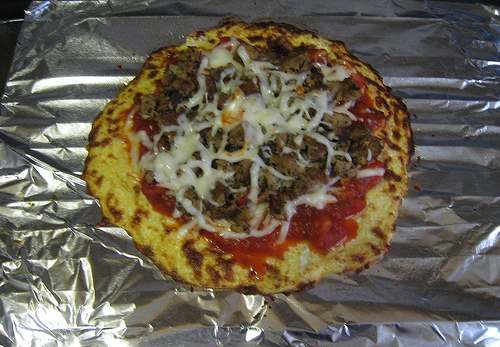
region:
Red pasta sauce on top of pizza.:
[277, 242, 328, 243]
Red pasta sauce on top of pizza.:
[234, 261, 285, 286]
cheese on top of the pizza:
[140, 44, 335, 250]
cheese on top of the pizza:
[135, 46, 319, 226]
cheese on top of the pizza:
[160, 59, 333, 244]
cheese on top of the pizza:
[166, 83, 324, 213]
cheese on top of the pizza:
[152, 61, 319, 237]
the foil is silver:
[14, 31, 114, 336]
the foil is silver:
[358, 139, 444, 341]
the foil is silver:
[375, 185, 460, 340]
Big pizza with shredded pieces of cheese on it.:
[275, 134, 320, 181]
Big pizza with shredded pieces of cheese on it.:
[52, 133, 100, 199]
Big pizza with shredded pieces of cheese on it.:
[303, 97, 325, 141]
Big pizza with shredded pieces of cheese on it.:
[290, 190, 307, 325]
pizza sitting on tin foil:
[6, 5, 499, 344]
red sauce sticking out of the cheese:
[216, 232, 282, 272]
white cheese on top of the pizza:
[135, 45, 385, 240]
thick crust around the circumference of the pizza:
[75, 15, 424, 290]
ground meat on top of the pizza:
[120, 38, 390, 236]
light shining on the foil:
[16, 270, 127, 342]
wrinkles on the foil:
[0, 0, 499, 344]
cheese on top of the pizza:
[138, 32, 385, 254]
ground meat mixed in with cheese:
[104, 28, 401, 248]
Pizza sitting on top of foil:
[85, 18, 416, 295]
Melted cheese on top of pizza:
[128, 40, 385, 242]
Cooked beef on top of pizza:
[143, 52, 204, 117]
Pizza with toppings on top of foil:
[85, 22, 417, 297]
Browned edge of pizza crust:
[365, 70, 410, 190]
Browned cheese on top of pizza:
[215, 85, 245, 126]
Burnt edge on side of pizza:
[225, 20, 315, 40]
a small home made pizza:
[84, 19, 416, 298]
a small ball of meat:
[136, 91, 156, 115]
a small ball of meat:
[329, 113, 351, 130]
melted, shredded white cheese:
[142, 39, 364, 234]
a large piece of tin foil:
[12, 3, 496, 343]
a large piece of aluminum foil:
[7, 2, 499, 344]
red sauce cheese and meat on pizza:
[90, 85, 150, 127]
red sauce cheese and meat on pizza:
[106, 175, 183, 258]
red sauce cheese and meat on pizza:
[233, 186, 312, 306]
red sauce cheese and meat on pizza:
[306, 207, 361, 262]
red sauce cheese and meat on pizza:
[301, 128, 370, 203]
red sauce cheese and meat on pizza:
[208, 189, 245, 258]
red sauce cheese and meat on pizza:
[275, 94, 330, 168]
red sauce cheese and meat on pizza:
[161, 87, 201, 139]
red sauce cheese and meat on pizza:
[261, 70, 312, 112]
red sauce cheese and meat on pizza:
[157, 109, 207, 164]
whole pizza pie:
[84, 15, 413, 294]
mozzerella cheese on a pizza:
[135, 38, 381, 238]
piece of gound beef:
[139, 91, 154, 119]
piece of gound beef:
[145, 170, 154, 182]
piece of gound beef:
[354, 133, 381, 165]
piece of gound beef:
[343, 118, 370, 140]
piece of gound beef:
[283, 40, 310, 71]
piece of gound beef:
[306, 138, 326, 158]